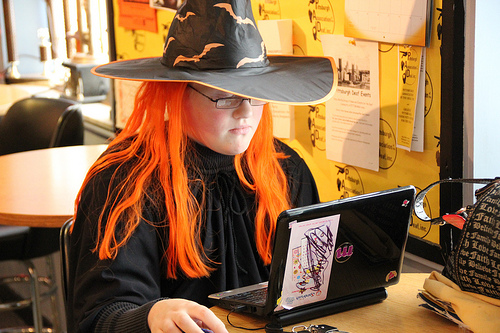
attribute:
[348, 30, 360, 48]
pin — yellow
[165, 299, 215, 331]
hand — using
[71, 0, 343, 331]
kid — wearing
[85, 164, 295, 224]
cape — black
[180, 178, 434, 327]
laptop — black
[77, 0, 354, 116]
hat — black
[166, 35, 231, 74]
bat — orange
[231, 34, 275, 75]
bat — orange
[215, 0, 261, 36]
bat — orange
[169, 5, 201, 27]
bat — orange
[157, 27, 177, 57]
bat — orange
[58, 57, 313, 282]
hair — neon orange, orange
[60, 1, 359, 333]
woman — young, dressed up, seated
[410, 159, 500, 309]
purse — black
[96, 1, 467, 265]
bulletin board — yellow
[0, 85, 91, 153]
chair — black, empty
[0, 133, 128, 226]
table — round